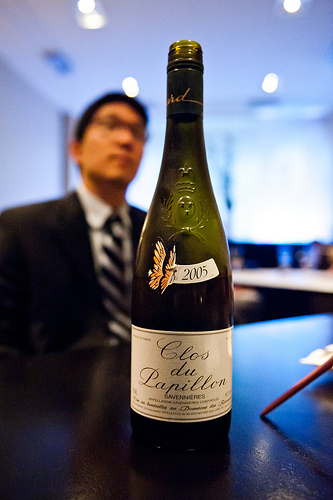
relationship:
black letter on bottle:
[177, 344, 193, 360] [131, 39, 230, 454]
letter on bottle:
[136, 366, 159, 387] [131, 39, 230, 454]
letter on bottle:
[155, 379, 164, 390] [131, 39, 230, 454]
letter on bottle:
[163, 381, 178, 394] [131, 39, 230, 454]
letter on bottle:
[180, 379, 189, 389] [131, 39, 230, 454]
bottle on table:
[131, 39, 230, 481] [2, 300, 330, 498]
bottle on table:
[131, 39, 230, 481] [232, 262, 331, 297]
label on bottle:
[129, 323, 231, 424] [121, 36, 240, 485]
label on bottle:
[148, 241, 219, 291] [131, 39, 230, 481]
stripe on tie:
[100, 227, 131, 340] [98, 215, 131, 343]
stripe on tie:
[97, 240, 128, 283] [95, 210, 138, 347]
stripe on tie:
[104, 308, 133, 334] [95, 207, 131, 350]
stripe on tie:
[97, 240, 128, 283] [98, 204, 130, 343]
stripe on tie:
[101, 223, 122, 247] [98, 215, 131, 343]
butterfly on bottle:
[146, 235, 177, 296] [131, 39, 230, 481]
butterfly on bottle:
[146, 235, 177, 296] [124, 30, 240, 449]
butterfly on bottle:
[146, 235, 177, 296] [121, 36, 240, 485]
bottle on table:
[131, 39, 230, 454] [2, 300, 330, 498]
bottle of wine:
[131, 39, 230, 454] [130, 40, 229, 470]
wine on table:
[117, 37, 235, 444] [2, 300, 330, 498]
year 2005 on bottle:
[181, 263, 207, 280] [131, 39, 230, 454]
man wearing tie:
[1, 86, 166, 364] [96, 207, 133, 345]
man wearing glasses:
[1, 86, 166, 364] [89, 112, 150, 146]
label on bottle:
[129, 323, 231, 424] [131, 39, 230, 454]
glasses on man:
[92, 115, 153, 145] [1, 86, 166, 364]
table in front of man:
[2, 300, 330, 498] [1, 86, 166, 364]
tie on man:
[99, 213, 131, 321] [1, 86, 166, 364]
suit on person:
[0, 187, 155, 357] [0, 90, 149, 350]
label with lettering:
[129, 323, 231, 424] [133, 334, 227, 413]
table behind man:
[231, 267, 331, 294] [1, 86, 166, 364]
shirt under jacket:
[75, 179, 136, 345] [0, 187, 145, 354]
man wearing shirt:
[1, 86, 166, 364] [75, 179, 136, 345]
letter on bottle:
[136, 366, 159, 387] [124, 30, 240, 449]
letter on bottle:
[163, 381, 178, 394] [131, 39, 230, 481]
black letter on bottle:
[137, 337, 230, 394] [121, 36, 240, 485]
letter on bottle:
[200, 370, 216, 393] [128, 36, 235, 498]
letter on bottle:
[169, 357, 194, 380] [131, 39, 230, 454]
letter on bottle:
[156, 339, 181, 358] [124, 30, 240, 449]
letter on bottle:
[188, 346, 202, 364] [134, 38, 265, 396]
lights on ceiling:
[261, 73, 279, 94] [224, 18, 295, 89]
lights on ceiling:
[281, 0, 302, 14] [224, 18, 295, 89]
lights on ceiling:
[121, 76, 138, 97] [224, 18, 295, 89]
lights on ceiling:
[75, 0, 104, 28] [224, 18, 295, 89]